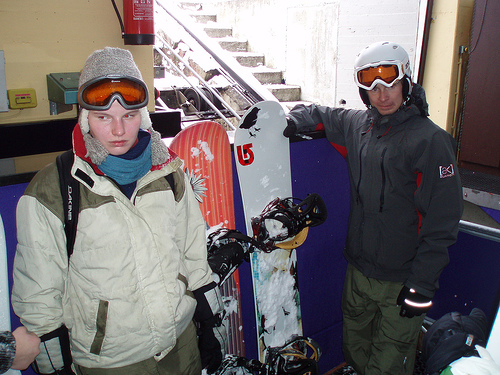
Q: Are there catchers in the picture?
A: No, there are no catchers.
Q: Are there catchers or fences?
A: No, there are no catchers or fences.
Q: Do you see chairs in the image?
A: No, there are no chairs.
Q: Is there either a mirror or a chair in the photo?
A: No, there are no chairs or mirrors.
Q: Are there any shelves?
A: No, there are no shelves.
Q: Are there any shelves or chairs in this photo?
A: No, there are no shelves or chairs.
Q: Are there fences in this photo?
A: No, there are no fences.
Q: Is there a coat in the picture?
A: Yes, there is a coat.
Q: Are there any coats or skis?
A: Yes, there is a coat.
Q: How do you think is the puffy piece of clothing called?
A: The clothing item is a coat.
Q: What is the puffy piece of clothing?
A: The clothing item is a coat.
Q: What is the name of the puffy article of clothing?
A: The clothing item is a coat.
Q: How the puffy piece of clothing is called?
A: The clothing item is a coat.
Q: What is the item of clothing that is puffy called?
A: The clothing item is a coat.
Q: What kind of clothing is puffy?
A: The clothing is a coat.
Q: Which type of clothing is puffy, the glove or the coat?
A: The coat is puffy.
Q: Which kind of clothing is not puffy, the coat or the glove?
A: The glove is not puffy.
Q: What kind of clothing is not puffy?
A: The clothing is a glove.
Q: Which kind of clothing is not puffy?
A: The clothing is a glove.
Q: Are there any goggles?
A: Yes, there are goggles.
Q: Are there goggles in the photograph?
A: Yes, there are goggles.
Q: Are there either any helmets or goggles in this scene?
A: Yes, there are goggles.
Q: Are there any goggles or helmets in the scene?
A: Yes, there are goggles.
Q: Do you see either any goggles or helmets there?
A: Yes, there are goggles.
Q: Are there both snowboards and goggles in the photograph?
A: Yes, there are both goggles and a snowboard.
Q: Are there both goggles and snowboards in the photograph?
A: Yes, there are both goggles and a snowboard.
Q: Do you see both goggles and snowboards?
A: Yes, there are both goggles and a snowboard.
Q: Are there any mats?
A: No, there are no mats.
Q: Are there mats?
A: No, there are no mats.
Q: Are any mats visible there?
A: No, there are no mats.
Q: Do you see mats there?
A: No, there are no mats.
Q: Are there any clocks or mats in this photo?
A: No, there are no mats or clocks.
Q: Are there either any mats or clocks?
A: No, there are no mats or clocks.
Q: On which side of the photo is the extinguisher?
A: The extinguisher is on the left of the image.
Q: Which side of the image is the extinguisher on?
A: The extinguisher is on the left of the image.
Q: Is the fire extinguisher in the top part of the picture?
A: Yes, the fire extinguisher is in the top of the image.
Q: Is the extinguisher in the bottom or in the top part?
A: The extinguisher is in the top of the image.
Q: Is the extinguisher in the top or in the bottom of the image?
A: The extinguisher is in the top of the image.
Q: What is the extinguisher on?
A: The extinguisher is on the wall.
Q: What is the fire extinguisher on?
A: The extinguisher is on the wall.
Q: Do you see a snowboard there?
A: Yes, there is a snowboard.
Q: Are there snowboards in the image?
A: Yes, there is a snowboard.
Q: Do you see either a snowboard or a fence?
A: Yes, there is a snowboard.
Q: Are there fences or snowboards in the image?
A: Yes, there is a snowboard.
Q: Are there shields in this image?
A: No, there are no shields.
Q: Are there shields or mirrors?
A: No, there are no shields or mirrors.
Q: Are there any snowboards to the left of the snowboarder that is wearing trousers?
A: Yes, there is a snowboard to the left of the snowboarder.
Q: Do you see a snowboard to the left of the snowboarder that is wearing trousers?
A: Yes, there is a snowboard to the left of the snowboarder.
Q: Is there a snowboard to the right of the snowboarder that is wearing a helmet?
A: No, the snowboard is to the left of the snowboarder.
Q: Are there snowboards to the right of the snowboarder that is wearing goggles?
A: Yes, there is a snowboard to the right of the snowboarder.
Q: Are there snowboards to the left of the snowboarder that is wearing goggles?
A: No, the snowboard is to the right of the snowboarder.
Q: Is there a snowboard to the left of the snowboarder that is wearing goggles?
A: No, the snowboard is to the right of the snowboarder.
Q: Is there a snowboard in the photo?
A: Yes, there is a snowboard.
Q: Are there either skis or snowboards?
A: Yes, there is a snowboard.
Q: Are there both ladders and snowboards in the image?
A: No, there is a snowboard but no ladders.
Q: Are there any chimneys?
A: No, there are no chimneys.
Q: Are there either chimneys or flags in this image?
A: No, there are no chimneys or flags.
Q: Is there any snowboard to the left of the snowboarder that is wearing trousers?
A: Yes, there is a snowboard to the left of the snowboarder.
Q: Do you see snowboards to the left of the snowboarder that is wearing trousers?
A: Yes, there is a snowboard to the left of the snowboarder.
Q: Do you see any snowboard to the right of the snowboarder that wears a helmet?
A: No, the snowboard is to the left of the snowboarder.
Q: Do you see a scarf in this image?
A: Yes, there is a scarf.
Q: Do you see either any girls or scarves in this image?
A: Yes, there is a scarf.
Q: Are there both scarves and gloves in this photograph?
A: Yes, there are both a scarf and gloves.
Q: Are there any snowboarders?
A: Yes, there is a snowboarder.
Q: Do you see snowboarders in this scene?
A: Yes, there is a snowboarder.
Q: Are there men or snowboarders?
A: Yes, there is a snowboarder.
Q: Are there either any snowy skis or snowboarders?
A: Yes, there is a snowy snowboarder.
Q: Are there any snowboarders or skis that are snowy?
A: Yes, the snowboarder is snowy.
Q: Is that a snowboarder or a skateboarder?
A: That is a snowboarder.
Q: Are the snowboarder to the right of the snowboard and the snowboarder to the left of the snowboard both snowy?
A: Yes, both the snowboarder and the snowboarder are snowy.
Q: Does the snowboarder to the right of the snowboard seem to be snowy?
A: Yes, the snowboarder is snowy.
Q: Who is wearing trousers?
A: The snowboarder is wearing trousers.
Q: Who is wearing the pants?
A: The snowboarder is wearing trousers.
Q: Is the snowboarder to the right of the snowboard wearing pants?
A: Yes, the snowboarder is wearing pants.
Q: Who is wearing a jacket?
A: The snowboarder is wearing a jacket.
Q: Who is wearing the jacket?
A: The snowboarder is wearing a jacket.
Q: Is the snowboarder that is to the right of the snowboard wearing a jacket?
A: Yes, the snowboarder is wearing a jacket.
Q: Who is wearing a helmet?
A: The snowboarder is wearing a helmet.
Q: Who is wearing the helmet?
A: The snowboarder is wearing a helmet.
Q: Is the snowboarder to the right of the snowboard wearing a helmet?
A: Yes, the snowboarder is wearing a helmet.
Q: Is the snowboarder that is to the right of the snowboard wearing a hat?
A: No, the snowboarder is wearing a helmet.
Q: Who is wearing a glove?
A: The snowboarder is wearing a glove.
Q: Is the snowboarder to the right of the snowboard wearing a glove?
A: Yes, the snowboarder is wearing a glove.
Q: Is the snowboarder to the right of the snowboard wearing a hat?
A: No, the snowboarder is wearing a glove.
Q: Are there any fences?
A: No, there are no fences.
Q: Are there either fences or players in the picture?
A: No, there are no fences or players.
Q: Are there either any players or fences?
A: No, there are no fences or players.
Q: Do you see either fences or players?
A: No, there are no fences or players.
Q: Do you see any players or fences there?
A: No, there are no fences or players.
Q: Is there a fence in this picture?
A: No, there are no fences.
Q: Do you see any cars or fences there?
A: No, there are no fences or cars.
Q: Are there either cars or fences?
A: No, there are no fences or cars.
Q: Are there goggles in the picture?
A: Yes, there are goggles.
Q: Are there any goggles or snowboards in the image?
A: Yes, there are goggles.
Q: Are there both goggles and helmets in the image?
A: Yes, there are both goggles and a helmet.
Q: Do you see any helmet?
A: Yes, there is a helmet.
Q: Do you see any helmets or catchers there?
A: Yes, there is a helmet.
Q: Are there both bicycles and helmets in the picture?
A: No, there is a helmet but no bikes.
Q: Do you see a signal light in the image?
A: No, there are no traffic lights.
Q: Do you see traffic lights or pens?
A: No, there are no traffic lights or pens.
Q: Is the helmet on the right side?
A: Yes, the helmet is on the right of the image.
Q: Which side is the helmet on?
A: The helmet is on the right of the image.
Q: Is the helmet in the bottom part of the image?
A: No, the helmet is in the top of the image.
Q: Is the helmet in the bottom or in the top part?
A: The helmet is in the top of the image.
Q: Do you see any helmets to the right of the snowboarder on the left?
A: Yes, there is a helmet to the right of the snowboarder.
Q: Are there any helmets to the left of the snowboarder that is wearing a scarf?
A: No, the helmet is to the right of the snowboarder.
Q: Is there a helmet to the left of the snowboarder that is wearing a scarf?
A: No, the helmet is to the right of the snowboarder.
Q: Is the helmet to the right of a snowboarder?
A: Yes, the helmet is to the right of a snowboarder.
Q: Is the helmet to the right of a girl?
A: No, the helmet is to the right of a snowboarder.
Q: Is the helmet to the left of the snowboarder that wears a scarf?
A: No, the helmet is to the right of the snowboarder.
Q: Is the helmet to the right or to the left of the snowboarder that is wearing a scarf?
A: The helmet is to the right of the snowboarder.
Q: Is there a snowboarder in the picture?
A: Yes, there is a snowboarder.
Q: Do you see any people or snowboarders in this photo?
A: Yes, there is a snowboarder.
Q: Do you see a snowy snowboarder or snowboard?
A: Yes, there is a snowy snowboarder.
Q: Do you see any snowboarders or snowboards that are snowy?
A: Yes, the snowboarder is snowy.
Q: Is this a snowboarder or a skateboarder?
A: This is a snowboarder.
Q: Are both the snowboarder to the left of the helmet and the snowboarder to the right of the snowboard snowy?
A: Yes, both the snowboarder and the snowboarder are snowy.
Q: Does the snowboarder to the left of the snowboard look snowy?
A: Yes, the snowboarder is snowy.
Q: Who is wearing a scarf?
A: The snowboarder is wearing a scarf.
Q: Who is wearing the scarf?
A: The snowboarder is wearing a scarf.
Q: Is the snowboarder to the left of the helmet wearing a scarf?
A: Yes, the snowboarder is wearing a scarf.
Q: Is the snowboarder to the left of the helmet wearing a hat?
A: No, the snowboarder is wearing a scarf.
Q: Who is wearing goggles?
A: The snowboarder is wearing goggles.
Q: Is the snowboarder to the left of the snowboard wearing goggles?
A: Yes, the snowboarder is wearing goggles.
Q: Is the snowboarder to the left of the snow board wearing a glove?
A: Yes, the snowboarder is wearing a glove.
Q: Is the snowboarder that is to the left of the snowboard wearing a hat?
A: No, the snowboarder is wearing a glove.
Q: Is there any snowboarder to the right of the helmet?
A: No, the snowboarder is to the left of the helmet.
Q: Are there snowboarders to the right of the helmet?
A: No, the snowboarder is to the left of the helmet.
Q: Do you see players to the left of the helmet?
A: No, there is a snowboarder to the left of the helmet.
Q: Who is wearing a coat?
A: The snowboarder is wearing a coat.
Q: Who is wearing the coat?
A: The snowboarder is wearing a coat.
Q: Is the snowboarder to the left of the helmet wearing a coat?
A: Yes, the snowboarder is wearing a coat.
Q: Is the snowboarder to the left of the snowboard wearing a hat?
A: No, the snowboarder is wearing a coat.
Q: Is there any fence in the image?
A: No, there are no fences.